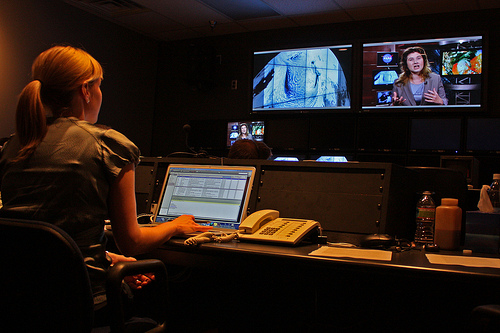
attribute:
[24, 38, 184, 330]
person — working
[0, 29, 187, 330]
person — watching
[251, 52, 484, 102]
screen — TV 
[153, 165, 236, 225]
monitor — computer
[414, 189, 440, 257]
bottle — water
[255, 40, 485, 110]
tv — large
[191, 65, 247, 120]
wall — side 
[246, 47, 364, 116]
tv — large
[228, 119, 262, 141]
monitor —  tv, small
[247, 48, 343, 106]
tv — upper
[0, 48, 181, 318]
woman — blonde, using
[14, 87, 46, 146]
tail — pony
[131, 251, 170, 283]
arm — black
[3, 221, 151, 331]
chair — rolling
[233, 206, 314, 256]
phone — small, white,  landline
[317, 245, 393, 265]
paper — piece, white,  small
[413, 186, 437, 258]
bottle — water, empty, clear 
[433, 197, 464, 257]
bottle — small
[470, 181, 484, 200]
tissue — sticking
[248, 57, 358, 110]
screen — tv , black, small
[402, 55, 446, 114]
woman — talking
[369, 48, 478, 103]
screen — tv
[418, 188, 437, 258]
bottle — water, plastic 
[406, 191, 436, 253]
bottle — plastic , water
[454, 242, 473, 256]
cap — missing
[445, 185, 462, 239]
bottle —  water ,  plastic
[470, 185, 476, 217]
bottle —  plastic,  water, white 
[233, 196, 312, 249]
telephone — white 